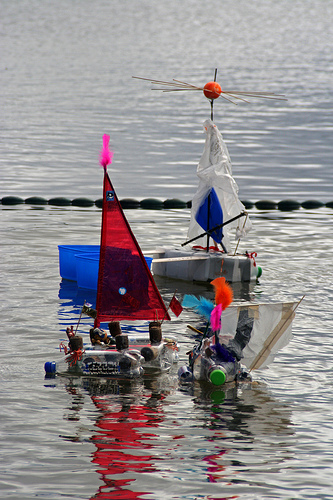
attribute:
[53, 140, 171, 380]
boat — floating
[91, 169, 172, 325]
sail — red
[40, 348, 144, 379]
bottle — floating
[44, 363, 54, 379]
cap — green, blue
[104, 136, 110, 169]
feather — pink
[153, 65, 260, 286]
boat — floating, handmade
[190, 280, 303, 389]
boat — floating, handmade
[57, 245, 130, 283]
tub — blue, floating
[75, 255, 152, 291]
tub — blue, floating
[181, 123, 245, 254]
sail — white